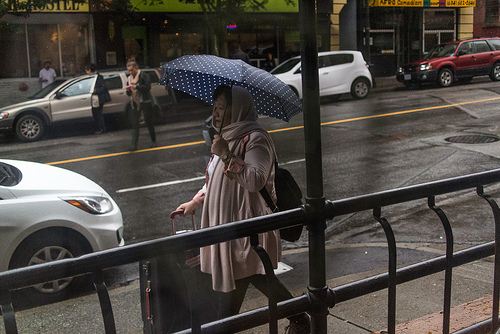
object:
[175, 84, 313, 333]
woman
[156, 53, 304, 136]
umbrella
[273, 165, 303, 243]
bag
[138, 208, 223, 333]
luggage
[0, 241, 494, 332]
sidewalk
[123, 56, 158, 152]
girl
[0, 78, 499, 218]
street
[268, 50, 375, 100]
car